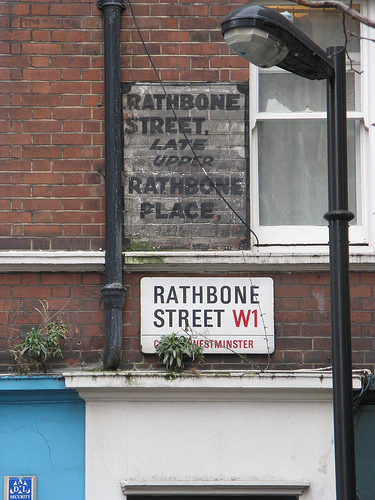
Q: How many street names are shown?
A: One.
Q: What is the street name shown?
A: Rathbone Street.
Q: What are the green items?
A: Plants.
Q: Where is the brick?
A: On the side of the building.